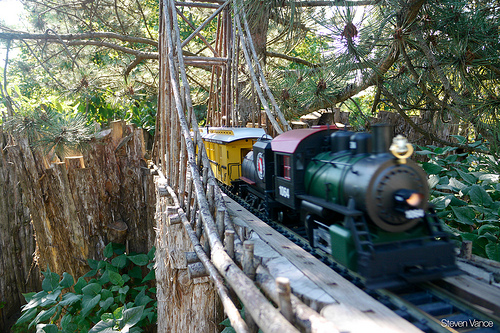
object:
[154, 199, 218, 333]
support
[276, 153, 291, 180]
window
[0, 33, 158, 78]
branch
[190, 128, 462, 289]
black train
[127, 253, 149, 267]
leaf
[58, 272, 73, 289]
leaf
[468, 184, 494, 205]
leaf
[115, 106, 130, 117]
leaf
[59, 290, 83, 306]
leaf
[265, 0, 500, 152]
tree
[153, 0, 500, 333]
bridge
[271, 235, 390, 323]
wood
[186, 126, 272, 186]
yellow train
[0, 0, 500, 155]
trees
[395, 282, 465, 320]
tracks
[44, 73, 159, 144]
trees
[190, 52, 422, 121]
trees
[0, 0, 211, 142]
trees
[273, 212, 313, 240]
train wheels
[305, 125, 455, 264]
train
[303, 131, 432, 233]
engine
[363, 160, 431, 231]
engine